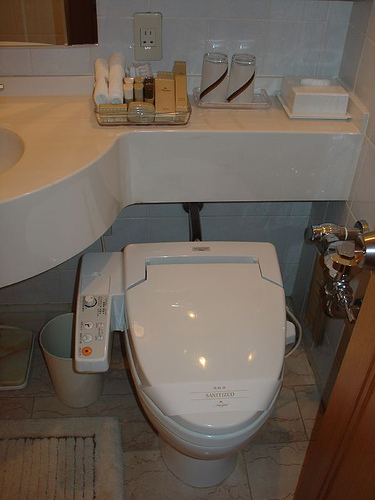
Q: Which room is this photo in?
A: It is at the bathroom.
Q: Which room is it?
A: It is a bathroom.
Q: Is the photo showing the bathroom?
A: Yes, it is showing the bathroom.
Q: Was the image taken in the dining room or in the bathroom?
A: It was taken at the bathroom.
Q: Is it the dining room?
A: No, it is the bathroom.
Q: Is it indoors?
A: Yes, it is indoors.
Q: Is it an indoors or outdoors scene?
A: It is indoors.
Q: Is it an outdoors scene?
A: No, it is indoors.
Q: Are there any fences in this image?
A: No, there are no fences.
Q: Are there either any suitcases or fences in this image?
A: No, there are no fences or suitcases.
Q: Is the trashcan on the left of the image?
A: Yes, the trashcan is on the left of the image.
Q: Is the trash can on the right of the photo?
A: No, the trash can is on the left of the image.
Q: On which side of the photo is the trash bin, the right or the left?
A: The trash bin is on the left of the image.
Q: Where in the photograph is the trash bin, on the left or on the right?
A: The trash bin is on the left of the image.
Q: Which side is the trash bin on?
A: The trash bin is on the left of the image.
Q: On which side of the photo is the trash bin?
A: The trash bin is on the left of the image.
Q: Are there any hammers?
A: No, there are no hammers.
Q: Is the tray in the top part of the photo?
A: Yes, the tray is in the top of the image.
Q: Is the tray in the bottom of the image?
A: No, the tray is in the top of the image.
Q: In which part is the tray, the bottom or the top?
A: The tray is in the top of the image.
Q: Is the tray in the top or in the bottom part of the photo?
A: The tray is in the top of the image.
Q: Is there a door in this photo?
A: Yes, there is a door.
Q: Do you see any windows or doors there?
A: Yes, there is a door.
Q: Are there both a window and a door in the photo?
A: No, there is a door but no windows.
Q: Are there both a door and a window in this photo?
A: No, there is a door but no windows.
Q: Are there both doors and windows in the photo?
A: No, there is a door but no windows.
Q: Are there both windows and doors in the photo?
A: No, there is a door but no windows.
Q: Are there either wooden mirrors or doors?
A: Yes, there is a wood door.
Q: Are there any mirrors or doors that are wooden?
A: Yes, the door is wooden.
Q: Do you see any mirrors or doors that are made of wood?
A: Yes, the door is made of wood.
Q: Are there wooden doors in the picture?
A: Yes, there is a wood door.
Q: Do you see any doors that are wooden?
A: Yes, there is a door that is wooden.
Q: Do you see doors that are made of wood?
A: Yes, there is a door that is made of wood.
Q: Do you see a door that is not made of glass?
A: Yes, there is a door that is made of wood.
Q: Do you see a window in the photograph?
A: No, there are no windows.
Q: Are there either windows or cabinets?
A: No, there are no windows or cabinets.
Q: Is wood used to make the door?
A: Yes, the door is made of wood.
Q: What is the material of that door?
A: The door is made of wood.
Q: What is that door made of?
A: The door is made of wood.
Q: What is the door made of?
A: The door is made of wood.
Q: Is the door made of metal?
A: No, the door is made of wood.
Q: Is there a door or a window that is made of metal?
A: No, there is a door but it is made of wood.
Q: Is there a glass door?
A: No, there is a door but it is made of wood.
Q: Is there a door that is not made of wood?
A: No, there is a door but it is made of wood.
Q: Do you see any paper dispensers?
A: No, there are no paper dispensers.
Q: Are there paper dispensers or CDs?
A: No, there are no paper dispensers or cds.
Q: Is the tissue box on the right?
A: Yes, the tissue box is on the right of the image.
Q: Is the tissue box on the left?
A: No, the tissue box is on the right of the image.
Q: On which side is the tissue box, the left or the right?
A: The tissue box is on the right of the image.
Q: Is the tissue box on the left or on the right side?
A: The tissue box is on the right of the image.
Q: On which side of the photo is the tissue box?
A: The tissue box is on the right of the image.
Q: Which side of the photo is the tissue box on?
A: The tissue box is on the right of the image.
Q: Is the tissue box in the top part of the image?
A: Yes, the tissue box is in the top of the image.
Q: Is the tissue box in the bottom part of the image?
A: No, the tissue box is in the top of the image.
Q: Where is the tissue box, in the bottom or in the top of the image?
A: The tissue box is in the top of the image.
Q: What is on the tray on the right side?
A: The tissue box is on the tray.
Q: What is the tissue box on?
A: The tissue box is on the tray.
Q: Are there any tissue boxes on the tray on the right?
A: Yes, there is a tissue box on the tray.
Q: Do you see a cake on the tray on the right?
A: No, there is a tissue box on the tray.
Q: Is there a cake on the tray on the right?
A: No, there is a tissue box on the tray.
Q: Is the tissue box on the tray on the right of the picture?
A: Yes, the tissue box is on the tray.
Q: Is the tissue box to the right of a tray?
A: Yes, the tissue box is to the right of a tray.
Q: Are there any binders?
A: No, there are no binders.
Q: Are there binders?
A: No, there are no binders.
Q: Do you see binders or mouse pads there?
A: No, there are no binders or mouse pads.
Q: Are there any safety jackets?
A: No, there are no safety jackets.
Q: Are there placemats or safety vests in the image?
A: No, there are no safety vests or placemats.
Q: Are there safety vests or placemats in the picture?
A: No, there are no safety vests or placemats.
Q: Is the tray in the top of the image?
A: Yes, the tray is in the top of the image.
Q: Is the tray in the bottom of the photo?
A: No, the tray is in the top of the image.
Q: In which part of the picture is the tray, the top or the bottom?
A: The tray is in the top of the image.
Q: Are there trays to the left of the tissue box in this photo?
A: Yes, there is a tray to the left of the tissue box.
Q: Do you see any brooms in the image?
A: No, there are no brooms.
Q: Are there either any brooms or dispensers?
A: No, there are no brooms or dispensers.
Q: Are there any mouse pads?
A: No, there are no mouse pads.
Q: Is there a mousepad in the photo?
A: No, there are no mouse pads.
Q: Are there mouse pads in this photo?
A: No, there are no mouse pads.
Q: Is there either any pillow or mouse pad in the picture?
A: No, there are no mouse pads or pillows.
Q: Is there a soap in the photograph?
A: Yes, there is a soap.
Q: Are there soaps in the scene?
A: Yes, there is a soap.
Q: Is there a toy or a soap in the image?
A: Yes, there is a soap.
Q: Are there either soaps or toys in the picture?
A: Yes, there is a soap.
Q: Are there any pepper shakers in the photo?
A: No, there are no pepper shakers.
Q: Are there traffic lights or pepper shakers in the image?
A: No, there are no pepper shakers or traffic lights.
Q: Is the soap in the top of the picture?
A: Yes, the soap is in the top of the image.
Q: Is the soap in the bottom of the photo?
A: No, the soap is in the top of the image.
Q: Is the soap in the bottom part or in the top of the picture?
A: The soap is in the top of the image.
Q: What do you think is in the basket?
A: The soap is in the basket.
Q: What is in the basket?
A: The soap is in the basket.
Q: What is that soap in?
A: The soap is in the basket.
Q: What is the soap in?
A: The soap is in the basket.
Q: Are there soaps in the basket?
A: Yes, there is a soap in the basket.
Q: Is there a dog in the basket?
A: No, there is a soap in the basket.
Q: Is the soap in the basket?
A: Yes, the soap is in the basket.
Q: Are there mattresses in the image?
A: No, there are no mattresses.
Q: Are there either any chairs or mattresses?
A: No, there are no mattresses or chairs.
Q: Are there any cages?
A: No, there are no cages.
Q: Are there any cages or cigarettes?
A: No, there are no cages or cigarettes.